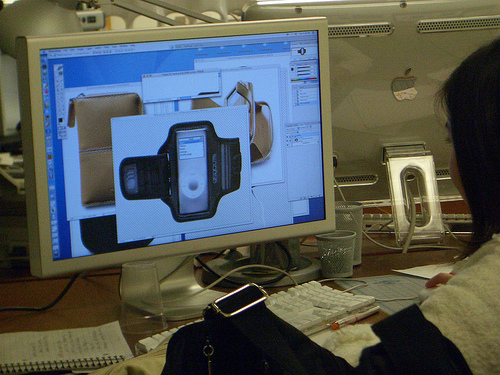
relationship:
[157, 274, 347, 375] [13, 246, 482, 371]
bag on desk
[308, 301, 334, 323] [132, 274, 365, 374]
key on keyboard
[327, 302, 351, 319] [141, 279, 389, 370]
key on keyboard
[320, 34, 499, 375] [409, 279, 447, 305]
lady using mouse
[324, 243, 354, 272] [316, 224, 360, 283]
paper clip inside cups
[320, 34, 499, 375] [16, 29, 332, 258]
lady looking at monitor